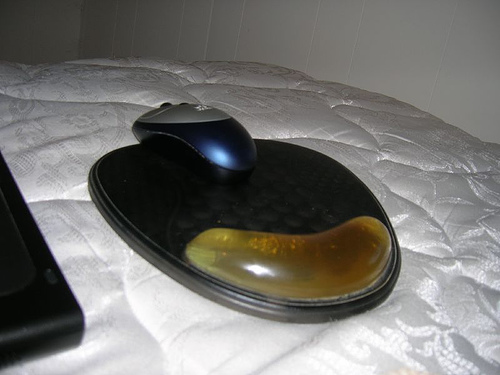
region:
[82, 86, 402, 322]
black mousepad on bed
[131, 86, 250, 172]
blue and grey mouse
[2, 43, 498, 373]
white mattress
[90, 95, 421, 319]
mouse and mouse pad sitting on bed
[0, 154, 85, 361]
black edge of laptop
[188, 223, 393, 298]
gel wrist rest on the mouse pad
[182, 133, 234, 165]
light reflected on mouse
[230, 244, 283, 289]
light reflected on wristrest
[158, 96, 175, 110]
scroller on top of mouse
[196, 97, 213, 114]
white lettering on mouse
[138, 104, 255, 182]
a wireless mouse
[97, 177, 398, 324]
a black mousepad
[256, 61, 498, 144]
part of a white mattress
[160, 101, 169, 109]
the center wheel of the mouse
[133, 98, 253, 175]
a dark blue and gray mouse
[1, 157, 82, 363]
part of a black laptop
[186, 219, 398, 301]
mousepad gelatinous tip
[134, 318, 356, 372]
light reflected on the mattress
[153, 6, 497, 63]
a wall with vertical bars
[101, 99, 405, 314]
an wireless mouse and a mousepad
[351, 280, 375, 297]
part of a mouse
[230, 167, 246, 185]
part of a mouse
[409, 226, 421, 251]
part of a blanket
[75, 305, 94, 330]
edge of a laptop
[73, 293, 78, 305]
edge of a laptop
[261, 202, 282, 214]
edge of a board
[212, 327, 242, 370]
edge of a bed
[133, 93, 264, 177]
Mouse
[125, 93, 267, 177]
Wireless mouse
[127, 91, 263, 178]
Blue wireless mouse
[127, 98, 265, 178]
Blue and grey wireless mouse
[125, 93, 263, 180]
Two button wireless mouse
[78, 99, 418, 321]
Wireless mouse on gel hand rest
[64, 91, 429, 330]
Wireless mouse on mouse pad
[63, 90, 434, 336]
Wireless mouse on pad on a blanket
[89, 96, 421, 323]
Black and amber gel mouse pad with mouse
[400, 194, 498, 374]
White blanket with stitched flower pattern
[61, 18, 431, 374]
a mouse on a mousepad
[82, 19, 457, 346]
a silver and blue mouse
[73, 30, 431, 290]
a silver and blue wireless mouse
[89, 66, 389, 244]
silver and blue computer mouse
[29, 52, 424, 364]
silver and blue computer wireless mouse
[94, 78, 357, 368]
a wireless computer mouse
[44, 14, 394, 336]
a mouse that is blue and silver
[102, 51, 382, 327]
a mouse that is wireless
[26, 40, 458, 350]
a mouse pad on a bed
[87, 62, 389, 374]
a mouse and a mouse pad